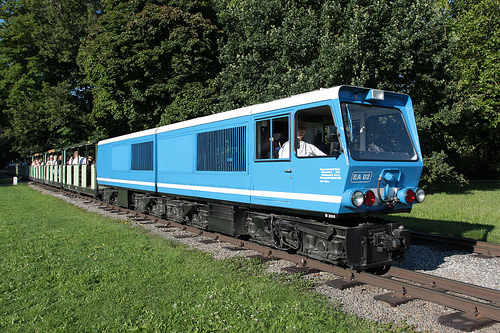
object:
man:
[278, 121, 327, 159]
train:
[6, 85, 425, 270]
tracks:
[28, 179, 500, 323]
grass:
[0, 245, 212, 332]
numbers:
[353, 174, 371, 181]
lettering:
[320, 168, 342, 183]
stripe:
[97, 177, 343, 203]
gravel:
[426, 251, 487, 279]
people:
[72, 150, 89, 164]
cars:
[63, 139, 100, 199]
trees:
[0, 2, 158, 93]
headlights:
[351, 190, 365, 207]